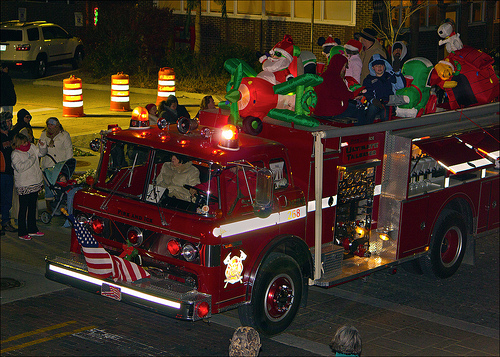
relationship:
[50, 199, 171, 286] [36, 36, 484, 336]
american flag on front of fire truck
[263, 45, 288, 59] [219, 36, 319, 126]
sunglasses on plush santa figure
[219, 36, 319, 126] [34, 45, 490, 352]
plush santa figure on fire truck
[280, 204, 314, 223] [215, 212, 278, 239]
numbers on white on white stripe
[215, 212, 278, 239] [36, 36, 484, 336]
white stripe on fire truck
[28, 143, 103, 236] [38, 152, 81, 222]
baby in stroller in stroller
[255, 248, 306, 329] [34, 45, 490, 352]
tire on fire truck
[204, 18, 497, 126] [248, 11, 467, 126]
engine carrying toys carrying toys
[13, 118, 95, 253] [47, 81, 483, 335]
people watching watching fire engine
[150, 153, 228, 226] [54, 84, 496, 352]
person driving driving fire engine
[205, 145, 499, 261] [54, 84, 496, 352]
stripe on fire engine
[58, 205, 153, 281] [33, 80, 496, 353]
american flag in front of truck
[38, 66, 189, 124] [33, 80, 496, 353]
cones on fire truck are on truck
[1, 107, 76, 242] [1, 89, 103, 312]
people standing standing in street corner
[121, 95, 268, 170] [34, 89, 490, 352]
lights on top of fire truck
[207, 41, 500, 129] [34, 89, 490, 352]
christmas balloons are on fire truck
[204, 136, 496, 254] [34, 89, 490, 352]
white stripe on fire truck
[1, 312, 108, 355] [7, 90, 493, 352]
yellow lines in street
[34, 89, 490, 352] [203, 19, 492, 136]
fire truck has christmas decoration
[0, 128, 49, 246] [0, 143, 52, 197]
woman wearing coat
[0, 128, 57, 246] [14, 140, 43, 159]
woman wearing red scarf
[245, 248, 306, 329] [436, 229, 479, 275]
tire has red hub cabs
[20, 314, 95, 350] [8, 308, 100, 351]
safety cones has yellow stripes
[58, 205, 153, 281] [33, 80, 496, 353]
american flag on top of truck